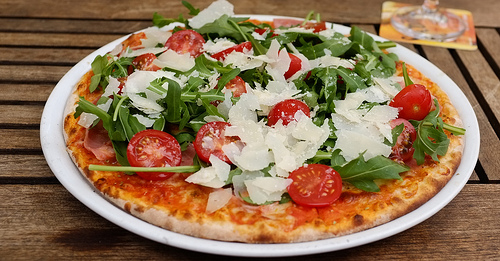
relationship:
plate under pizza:
[39, 13, 481, 256] [62, 1, 466, 245]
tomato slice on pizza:
[127, 131, 182, 180] [62, 1, 466, 245]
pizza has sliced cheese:
[62, 1, 466, 245] [79, 0, 404, 214]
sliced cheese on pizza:
[79, 0, 404, 214] [62, 1, 466, 245]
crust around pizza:
[62, 18, 466, 245] [62, 1, 466, 245]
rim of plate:
[41, 14, 481, 258] [39, 13, 481, 256]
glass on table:
[391, 2, 467, 43] [1, 1, 500, 261]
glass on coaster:
[391, 2, 467, 43] [378, 1, 478, 54]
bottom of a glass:
[390, 10, 469, 42] [391, 2, 467, 43]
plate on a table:
[39, 13, 481, 256] [1, 1, 500, 261]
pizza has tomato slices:
[62, 1, 466, 245] [119, 22, 432, 208]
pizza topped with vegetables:
[62, 1, 466, 245] [73, 0, 465, 214]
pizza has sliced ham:
[62, 1, 466, 245] [84, 116, 198, 177]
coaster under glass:
[378, 1, 478, 54] [391, 2, 467, 43]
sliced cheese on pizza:
[79, 24, 403, 214] [62, 1, 466, 245]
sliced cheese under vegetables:
[79, 24, 403, 214] [73, 0, 465, 214]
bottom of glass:
[390, 10, 469, 42] [391, 2, 467, 43]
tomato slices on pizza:
[119, 22, 432, 208] [62, 1, 466, 245]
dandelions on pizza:
[73, 1, 466, 194] [62, 1, 466, 245]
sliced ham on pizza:
[84, 116, 198, 177] [62, 1, 466, 245]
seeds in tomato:
[293, 171, 335, 197] [287, 164, 344, 208]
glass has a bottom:
[391, 2, 467, 43] [390, 10, 469, 42]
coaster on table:
[378, 1, 478, 54] [1, 1, 500, 261]